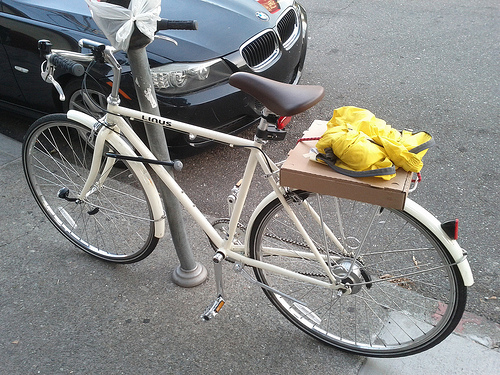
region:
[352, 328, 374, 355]
motorcycle in a field with gravel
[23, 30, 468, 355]
Bicycle leaning on post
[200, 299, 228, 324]
Silver pedal on a bicycle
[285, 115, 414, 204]
Cardboard box on back of bike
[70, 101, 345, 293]
White frame of a bicycle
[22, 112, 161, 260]
Front tire on a bike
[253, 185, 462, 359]
Back tire on a bike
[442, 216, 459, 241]
Reflector on the back fender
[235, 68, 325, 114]
Black seat on a bicycle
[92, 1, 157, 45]
Plastic wrapped around a pole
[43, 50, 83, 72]
Handlebar grip on bicycle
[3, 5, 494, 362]
bike parking on a street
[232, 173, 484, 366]
back wheel of bike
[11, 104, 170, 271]
front wheel of bike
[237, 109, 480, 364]
box on top a wheel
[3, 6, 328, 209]
black car parking on side the street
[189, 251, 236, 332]
pedal of bike is silver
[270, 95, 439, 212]
a yellow bag on top a box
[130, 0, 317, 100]
two headlights of car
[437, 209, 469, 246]
light on back a bike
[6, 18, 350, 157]
The car that is parked.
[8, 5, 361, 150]
The parked car is black.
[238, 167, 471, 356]
The back wheel of the bike.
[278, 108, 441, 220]
The cardboard box on the bike.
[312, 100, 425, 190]
The yellow material on the bike.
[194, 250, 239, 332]
The left pedal of the bike.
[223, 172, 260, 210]
The right pedal of the bike.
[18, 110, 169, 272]
The front wheel of the bike.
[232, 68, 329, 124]
The seat of the bike.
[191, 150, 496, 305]
The road is paved.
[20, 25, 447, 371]
the bike is parked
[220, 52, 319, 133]
the seat is brown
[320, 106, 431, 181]
The yellow item on the bike.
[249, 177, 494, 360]
The rear wheel of the bike.